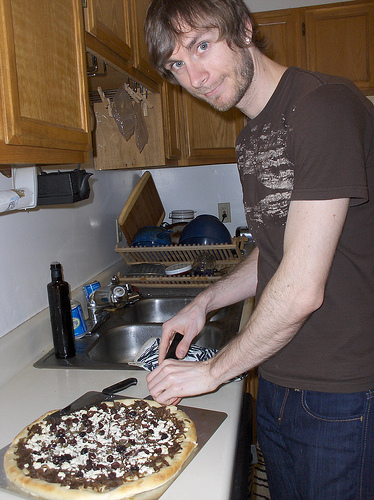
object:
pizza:
[3, 398, 199, 500]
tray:
[1, 390, 228, 500]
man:
[145, 1, 374, 500]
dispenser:
[0, 185, 25, 211]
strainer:
[115, 265, 243, 288]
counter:
[1, 366, 244, 500]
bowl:
[177, 213, 232, 241]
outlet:
[217, 202, 232, 223]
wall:
[0, 164, 140, 340]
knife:
[62, 377, 140, 416]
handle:
[100, 377, 137, 397]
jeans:
[256, 375, 374, 499]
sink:
[86, 324, 220, 368]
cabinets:
[2, 1, 95, 167]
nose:
[186, 57, 208, 90]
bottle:
[46, 260, 75, 358]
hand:
[147, 354, 217, 407]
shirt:
[236, 66, 374, 394]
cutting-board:
[117, 168, 166, 246]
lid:
[165, 262, 190, 275]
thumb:
[173, 332, 191, 360]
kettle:
[37, 168, 93, 206]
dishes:
[161, 261, 192, 275]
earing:
[243, 35, 252, 46]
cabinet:
[84, 0, 161, 89]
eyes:
[197, 39, 211, 55]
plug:
[219, 212, 227, 224]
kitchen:
[0, 0, 373, 500]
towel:
[131, 333, 220, 372]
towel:
[0, 189, 21, 211]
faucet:
[109, 286, 128, 306]